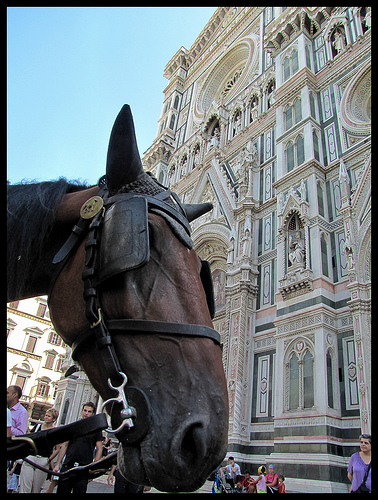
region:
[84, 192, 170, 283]
The horse is wearing blinders.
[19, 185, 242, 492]
The horse is wearing a harness.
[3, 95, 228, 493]
The horse is dark brown.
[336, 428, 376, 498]
A woman is standing in the background.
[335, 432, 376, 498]
The woman wears a purple top.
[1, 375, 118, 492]
People are standing in the background.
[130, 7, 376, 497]
A tall building is in the background.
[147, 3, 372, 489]
The building is very ornate.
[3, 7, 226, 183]
The sky is blue.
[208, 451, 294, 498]
A group of children are in the background.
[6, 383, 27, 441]
A man wearing a pink shirt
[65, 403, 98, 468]
A man wearing a black shirt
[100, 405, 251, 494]
A horse's nose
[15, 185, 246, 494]
A horse wearing a harness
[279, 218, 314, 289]
A statue on a building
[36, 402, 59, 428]
A woman that has short hair.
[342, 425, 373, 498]
A woman wearing a purple shirt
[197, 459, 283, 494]
People sitting on steps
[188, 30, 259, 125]
Large round window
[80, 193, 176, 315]
A horse that has his eyes covered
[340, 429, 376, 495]
a lady with a purple shirt and a black bag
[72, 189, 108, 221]
a round gold piece of the harnass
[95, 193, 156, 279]
the horse's blinder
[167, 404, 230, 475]
the horse's right nostril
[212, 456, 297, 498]
people sitting on the curb in front of the church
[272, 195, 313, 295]
a statue on the front of the church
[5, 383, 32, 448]
a man wearing a long sleeved pink shirt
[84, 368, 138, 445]
the silver metal clasp of the horse's bridle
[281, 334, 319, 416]
the stained glass window below the statue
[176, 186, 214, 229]
the horse's left ear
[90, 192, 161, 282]
a leather horse blinder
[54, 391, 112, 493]
a man dressed all in black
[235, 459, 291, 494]
a few kids sitting together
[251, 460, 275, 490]
a girl with yellow hat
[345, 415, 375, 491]
an elderly woman in purple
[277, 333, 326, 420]
some windows in an arch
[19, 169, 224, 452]
a leather horse bridle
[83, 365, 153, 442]
a leather bit snaffle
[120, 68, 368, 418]
a decoratively ornate building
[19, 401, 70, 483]
a woman in khaki pants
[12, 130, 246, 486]
an exteme close up of a horses face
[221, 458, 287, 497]
a group of people standing around a building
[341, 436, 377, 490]
a woman standing around by herself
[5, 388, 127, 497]
people standing in line next to the horse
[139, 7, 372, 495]
a tall building that people are standing by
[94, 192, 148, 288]
a blinder on the horse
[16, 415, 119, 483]
reins attached to the horse's harness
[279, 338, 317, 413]
a window in the building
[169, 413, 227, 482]
the nose of the horse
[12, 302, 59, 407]
another building on the side